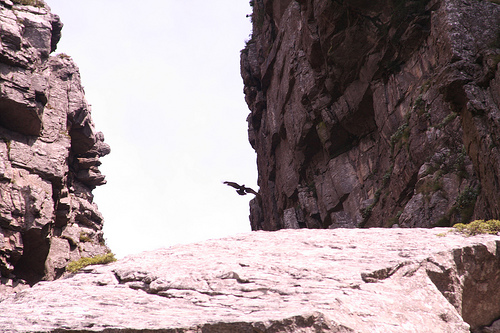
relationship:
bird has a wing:
[223, 181, 256, 197] [224, 181, 240, 191]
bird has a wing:
[223, 181, 256, 197] [244, 187, 257, 196]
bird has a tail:
[223, 181, 256, 197] [235, 189, 246, 196]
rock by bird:
[238, 0, 499, 231] [223, 181, 256, 197]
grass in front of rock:
[66, 251, 117, 274] [0, 1, 110, 289]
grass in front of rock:
[455, 218, 499, 237] [238, 0, 499, 231]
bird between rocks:
[223, 181, 256, 197] [0, 0, 498, 288]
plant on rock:
[13, 0, 45, 8] [0, 1, 110, 289]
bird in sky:
[223, 181, 256, 197] [47, 0, 253, 257]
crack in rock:
[354, 11, 383, 31] [238, 0, 499, 231]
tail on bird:
[235, 189, 246, 196] [223, 181, 256, 197]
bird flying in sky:
[223, 181, 256, 197] [47, 0, 253, 257]